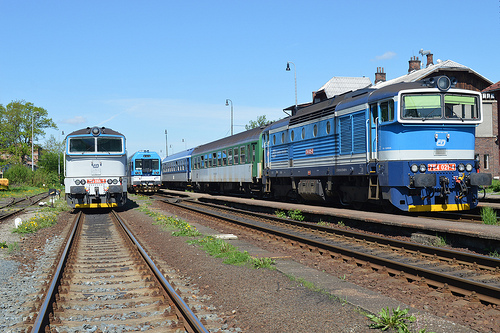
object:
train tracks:
[22, 209, 208, 331]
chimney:
[408, 55, 422, 73]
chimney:
[425, 53, 433, 67]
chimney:
[374, 66, 386, 83]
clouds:
[370, 47, 398, 63]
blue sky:
[0, 0, 499, 157]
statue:
[308, 74, 372, 101]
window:
[401, 93, 443, 119]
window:
[443, 93, 479, 120]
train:
[160, 75, 492, 212]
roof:
[313, 74, 373, 99]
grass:
[130, 192, 275, 273]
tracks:
[143, 182, 500, 305]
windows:
[211, 151, 217, 167]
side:
[191, 139, 262, 184]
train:
[56, 124, 132, 213]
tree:
[0, 100, 57, 165]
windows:
[238, 144, 248, 164]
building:
[23, 145, 41, 167]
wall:
[473, 97, 497, 179]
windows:
[68, 135, 96, 154]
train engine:
[265, 71, 482, 221]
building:
[475, 79, 500, 177]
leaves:
[22, 104, 24, 115]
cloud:
[55, 91, 284, 137]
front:
[380, 77, 485, 214]